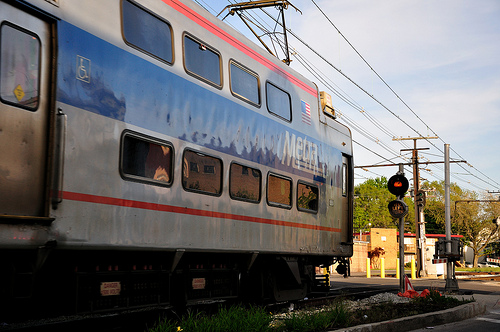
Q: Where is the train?
A: On the tracks.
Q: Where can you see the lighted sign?
A: On the right of train.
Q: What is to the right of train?
A: Grass inside of cement column.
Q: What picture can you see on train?
A: Handicapped picture.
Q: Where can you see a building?
A: Across the street behind train.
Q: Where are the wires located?
A: Above the train.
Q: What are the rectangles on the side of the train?
A: Window.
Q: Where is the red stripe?
A: On the side of the train.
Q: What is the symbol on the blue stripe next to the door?
A: Handicap.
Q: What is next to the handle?
A: Door.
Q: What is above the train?
A: Power lines.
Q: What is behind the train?
A: Intersection.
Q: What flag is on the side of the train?
A: Flag.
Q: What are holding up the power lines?
A: Poles.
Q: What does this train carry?
A: Passengers.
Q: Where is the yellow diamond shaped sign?
A: On the door window.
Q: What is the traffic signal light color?
A: Red.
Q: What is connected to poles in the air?
A: Wires.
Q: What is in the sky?
A: Clouds.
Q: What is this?
A: A trolley.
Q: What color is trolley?
A: Blue and silver.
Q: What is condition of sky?
A: Clear.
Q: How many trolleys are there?
A: One.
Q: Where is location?
A: In the city.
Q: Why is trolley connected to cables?
A: For power.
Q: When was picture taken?
A: During daylight.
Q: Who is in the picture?
A: No one.